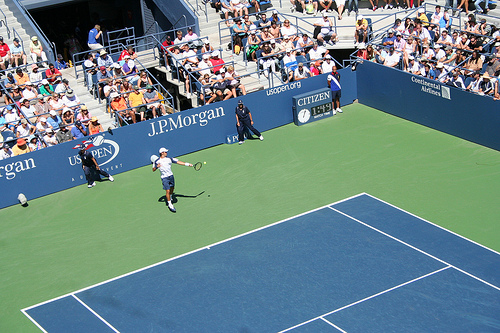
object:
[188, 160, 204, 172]
tennis raquet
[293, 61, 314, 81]
person sitting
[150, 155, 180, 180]
shirt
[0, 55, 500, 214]
partition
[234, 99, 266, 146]
ball boy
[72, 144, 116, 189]
ball boy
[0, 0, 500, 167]
spectator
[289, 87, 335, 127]
clock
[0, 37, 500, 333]
tennis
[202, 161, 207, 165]
ball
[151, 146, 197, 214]
man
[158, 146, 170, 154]
hat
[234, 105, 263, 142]
clothes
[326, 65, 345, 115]
man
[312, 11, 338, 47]
person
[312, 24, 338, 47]
chair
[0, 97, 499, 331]
court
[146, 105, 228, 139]
advertisement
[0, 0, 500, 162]
bleachers